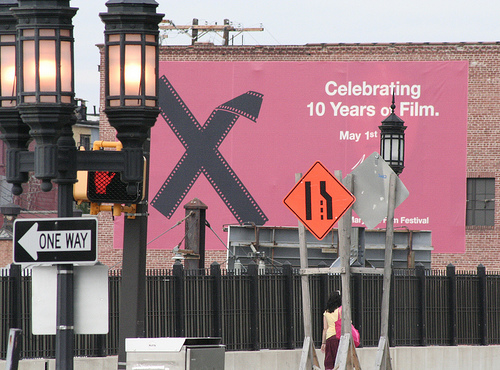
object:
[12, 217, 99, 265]
traffic sign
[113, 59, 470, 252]
sign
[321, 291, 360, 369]
woman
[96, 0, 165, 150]
street lights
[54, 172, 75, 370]
light pole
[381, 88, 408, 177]
street light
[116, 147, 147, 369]
pole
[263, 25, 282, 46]
lines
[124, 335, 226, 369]
box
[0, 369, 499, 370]
street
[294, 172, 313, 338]
pole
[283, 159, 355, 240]
sign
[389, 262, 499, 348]
fence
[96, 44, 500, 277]
building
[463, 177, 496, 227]
window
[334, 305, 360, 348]
purse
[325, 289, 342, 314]
her hair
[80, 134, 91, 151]
windows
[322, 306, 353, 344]
shirt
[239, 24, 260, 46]
power lines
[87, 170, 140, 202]
crosswalk signal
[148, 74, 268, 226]
painted x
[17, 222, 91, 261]
left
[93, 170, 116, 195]
hand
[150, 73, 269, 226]
film strips